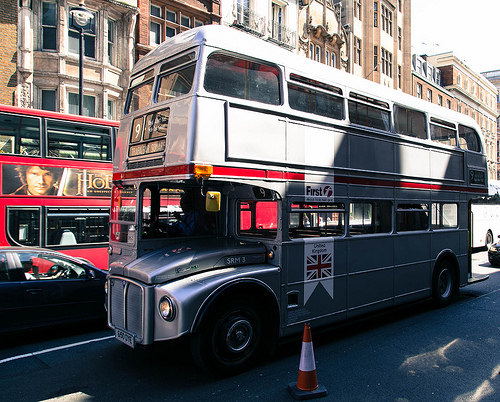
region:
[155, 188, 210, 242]
driver of a bus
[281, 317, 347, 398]
a cone on the street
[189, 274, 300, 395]
front wheel of a bus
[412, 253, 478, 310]
rear wheel of a bus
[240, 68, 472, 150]
windows of a bus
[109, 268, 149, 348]
front grill of a bus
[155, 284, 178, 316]
head lamp of a bus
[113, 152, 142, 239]
windshield of a bus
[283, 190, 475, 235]
windows on a bus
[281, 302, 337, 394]
a red and white cone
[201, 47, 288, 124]
Small window on a bus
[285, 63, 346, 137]
Small window on a bus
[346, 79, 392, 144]
Small window on a bus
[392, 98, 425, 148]
Small window on a bus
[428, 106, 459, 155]
Small window on a bus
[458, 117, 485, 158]
Small window on a bus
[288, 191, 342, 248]
Small window on a bus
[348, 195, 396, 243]
Small window on a bus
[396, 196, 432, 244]
Small window on a bus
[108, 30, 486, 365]
Large blue and white bus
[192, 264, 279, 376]
wheel of a bus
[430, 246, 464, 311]
wheel of a bus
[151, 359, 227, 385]
shadows of a bus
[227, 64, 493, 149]
top windows of a bus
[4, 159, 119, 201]
advertisement poster on bus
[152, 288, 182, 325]
headlight of a bus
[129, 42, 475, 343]
white and silver double decker bus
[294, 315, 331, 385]
white and orange traffic cone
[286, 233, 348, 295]
UK flag on bus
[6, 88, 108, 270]
red double decker bus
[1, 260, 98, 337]
black car between buses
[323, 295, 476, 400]
road is dark grey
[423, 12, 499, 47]
sky is grey and bright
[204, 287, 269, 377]
black wheels on bus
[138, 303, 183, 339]
white headlights on bus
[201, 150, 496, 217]
red stripe on bus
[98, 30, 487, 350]
large white two story bus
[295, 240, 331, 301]
sign on side of bus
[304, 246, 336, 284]
flag on side of bus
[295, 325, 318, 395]
traffic cone on street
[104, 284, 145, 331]
silver front of bus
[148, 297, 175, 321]
front light of bus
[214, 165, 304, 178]
red stripe on side of bus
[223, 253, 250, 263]
white number on side of bus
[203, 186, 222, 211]
side view mirrror on bus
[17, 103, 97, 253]
large red two story bus